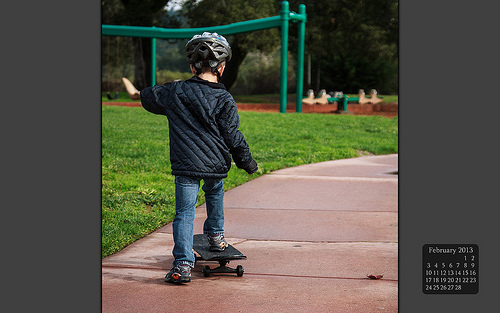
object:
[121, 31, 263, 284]
boy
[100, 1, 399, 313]
park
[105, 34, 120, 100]
black swing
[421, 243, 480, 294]
calendar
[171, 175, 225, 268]
blue jeans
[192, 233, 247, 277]
black skateboard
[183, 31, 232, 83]
helmet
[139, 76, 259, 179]
black jacket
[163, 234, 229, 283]
sneakers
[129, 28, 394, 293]
outdoors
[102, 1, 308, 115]
monkey bars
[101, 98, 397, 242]
grass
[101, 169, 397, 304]
sidewalk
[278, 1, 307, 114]
posts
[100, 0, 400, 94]
trees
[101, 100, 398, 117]
playground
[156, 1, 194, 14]
sky